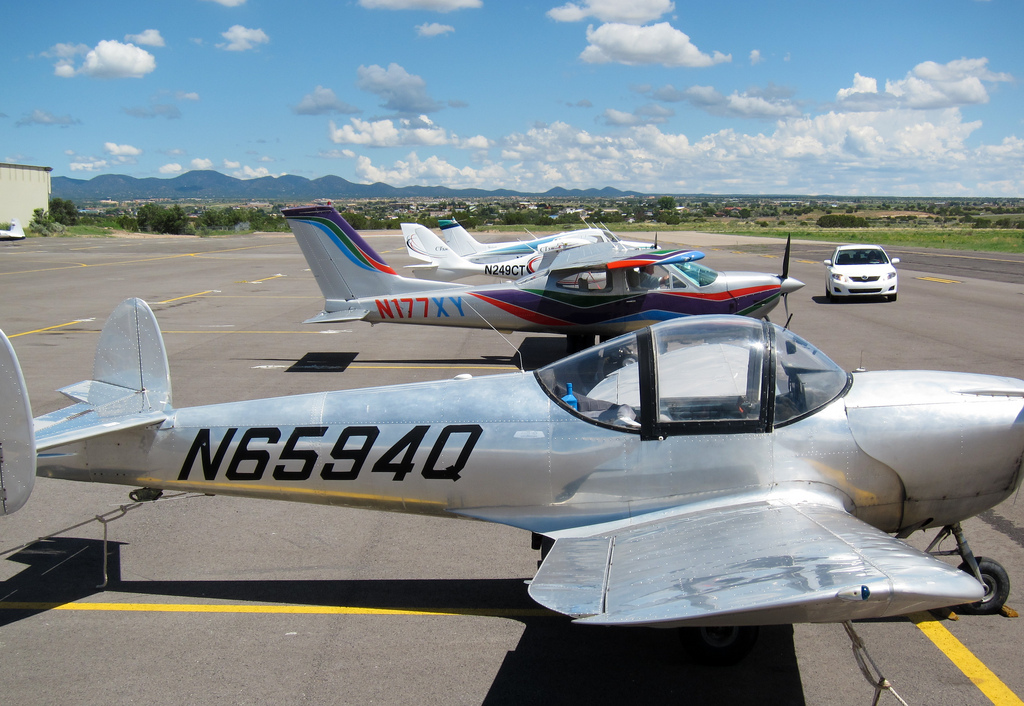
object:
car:
[829, 245, 902, 303]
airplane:
[443, 220, 664, 254]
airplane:
[11, 313, 1008, 633]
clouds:
[843, 126, 885, 162]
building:
[0, 164, 57, 234]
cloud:
[639, 107, 675, 119]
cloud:
[730, 96, 791, 122]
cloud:
[841, 89, 896, 114]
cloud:
[218, 21, 255, 52]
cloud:
[81, 38, 156, 79]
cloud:
[129, 29, 168, 49]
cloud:
[579, 22, 711, 69]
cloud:
[405, 24, 455, 41]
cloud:
[298, 89, 357, 115]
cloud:
[54, 60, 75, 79]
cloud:
[46, 40, 89, 58]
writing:
[187, 425, 479, 482]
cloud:
[83, 42, 154, 76]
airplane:
[307, 260, 799, 327]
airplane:
[397, 239, 663, 272]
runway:
[11, 233, 350, 597]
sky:
[0, 0, 1024, 182]